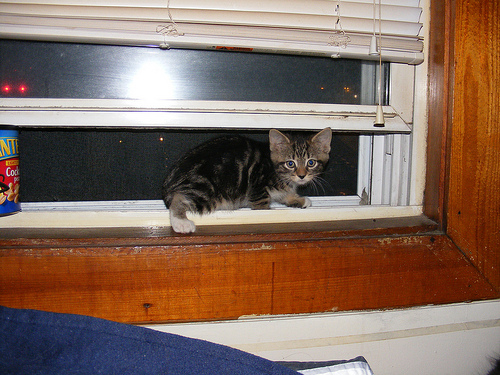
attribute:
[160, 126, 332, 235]
cat — grey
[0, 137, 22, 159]
brand name — yellow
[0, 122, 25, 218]
can — blue and red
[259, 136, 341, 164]
eyes — blue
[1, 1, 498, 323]
wood — worn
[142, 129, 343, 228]
cat — grey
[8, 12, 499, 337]
frame — wood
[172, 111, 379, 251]
cat — grey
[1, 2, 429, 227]
window — white, peeling, chipping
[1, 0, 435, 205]
window — white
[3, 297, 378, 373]
bedding — blue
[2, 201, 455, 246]
sill — window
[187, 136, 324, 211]
kitten — black, gray & white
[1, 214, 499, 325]
frame — wooden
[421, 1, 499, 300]
frame — wooden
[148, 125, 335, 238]
cat — grey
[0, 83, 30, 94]
lights — red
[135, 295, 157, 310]
knot — black